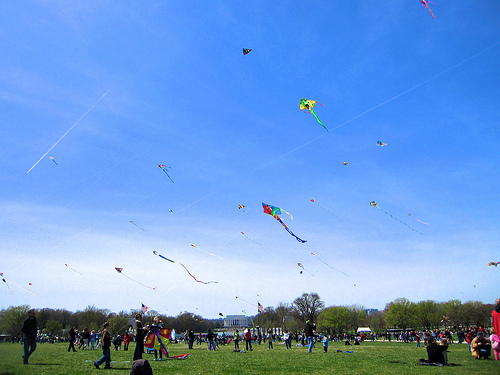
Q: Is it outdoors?
A: Yes, it is outdoors.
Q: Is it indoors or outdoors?
A: It is outdoors.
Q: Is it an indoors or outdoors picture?
A: It is outdoors.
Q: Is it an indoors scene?
A: No, it is outdoors.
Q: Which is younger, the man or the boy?
A: The boy is younger than the man.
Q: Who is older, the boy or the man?
A: The man is older than the boy.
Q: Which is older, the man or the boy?
A: The man is older than the boy.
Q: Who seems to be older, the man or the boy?
A: The man is older than the boy.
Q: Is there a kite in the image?
A: Yes, there is a kite.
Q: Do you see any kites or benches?
A: Yes, there is a kite.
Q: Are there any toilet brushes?
A: No, there are no toilet brushes.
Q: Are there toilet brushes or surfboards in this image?
A: No, there are no toilet brushes or surfboards.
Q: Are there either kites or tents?
A: Yes, there is a kite.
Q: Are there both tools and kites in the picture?
A: No, there is a kite but no tools.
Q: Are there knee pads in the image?
A: No, there are no knee pads.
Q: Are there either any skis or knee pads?
A: No, there are no knee pads or skis.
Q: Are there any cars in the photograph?
A: No, there are no cars.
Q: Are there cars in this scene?
A: No, there are no cars.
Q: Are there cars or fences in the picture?
A: No, there are no cars or fences.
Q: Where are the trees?
A: The trees are in the park.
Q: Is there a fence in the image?
A: No, there are no fences.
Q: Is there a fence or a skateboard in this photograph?
A: No, there are no fences or skateboards.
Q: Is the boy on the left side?
A: Yes, the boy is on the left of the image.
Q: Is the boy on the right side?
A: No, the boy is on the left of the image.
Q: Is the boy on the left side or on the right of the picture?
A: The boy is on the left of the image.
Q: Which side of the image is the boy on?
A: The boy is on the left of the image.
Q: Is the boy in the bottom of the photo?
A: Yes, the boy is in the bottom of the image.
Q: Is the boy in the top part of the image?
A: No, the boy is in the bottom of the image.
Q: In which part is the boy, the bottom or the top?
A: The boy is in the bottom of the image.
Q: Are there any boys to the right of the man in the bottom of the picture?
A: Yes, there is a boy to the right of the man.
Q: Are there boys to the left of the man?
A: No, the boy is to the right of the man.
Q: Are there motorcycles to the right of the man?
A: No, there is a boy to the right of the man.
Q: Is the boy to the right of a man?
A: Yes, the boy is to the right of a man.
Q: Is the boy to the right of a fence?
A: No, the boy is to the right of a man.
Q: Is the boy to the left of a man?
A: No, the boy is to the right of a man.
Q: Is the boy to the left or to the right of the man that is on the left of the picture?
A: The boy is to the right of the man.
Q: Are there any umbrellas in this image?
A: No, there are no umbrellas.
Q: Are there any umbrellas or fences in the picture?
A: No, there are no umbrellas or fences.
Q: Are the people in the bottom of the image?
A: Yes, the people are in the bottom of the image.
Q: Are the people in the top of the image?
A: No, the people are in the bottom of the image.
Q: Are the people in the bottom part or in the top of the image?
A: The people are in the bottom of the image.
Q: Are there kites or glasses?
A: Yes, there is a kite.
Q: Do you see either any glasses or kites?
A: Yes, there is a kite.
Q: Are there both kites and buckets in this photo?
A: No, there is a kite but no buckets.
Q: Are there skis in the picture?
A: No, there are no skis.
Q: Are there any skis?
A: No, there are no skis.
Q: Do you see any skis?
A: No, there are no skis.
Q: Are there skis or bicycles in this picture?
A: No, there are no skis or bicycles.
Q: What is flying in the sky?
A: The kite is flying in the sky.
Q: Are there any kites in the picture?
A: Yes, there is a kite.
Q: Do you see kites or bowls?
A: Yes, there is a kite.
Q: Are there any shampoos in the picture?
A: No, there are no shampoos.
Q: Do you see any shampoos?
A: No, there are no shampoos.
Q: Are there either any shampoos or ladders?
A: No, there are no shampoos or ladders.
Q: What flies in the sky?
A: The kite flies in the sky.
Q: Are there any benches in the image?
A: No, there are no benches.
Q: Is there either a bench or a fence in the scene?
A: No, there are no benches or fences.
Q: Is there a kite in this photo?
A: Yes, there is a kite.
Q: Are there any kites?
A: Yes, there is a kite.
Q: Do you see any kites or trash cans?
A: Yes, there is a kite.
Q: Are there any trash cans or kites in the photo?
A: Yes, there is a kite.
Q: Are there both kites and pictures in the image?
A: No, there is a kite but no pictures.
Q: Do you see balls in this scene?
A: No, there are no balls.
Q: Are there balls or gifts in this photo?
A: No, there are no balls or gifts.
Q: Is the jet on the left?
A: Yes, the jet is on the left of the image.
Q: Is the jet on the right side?
A: No, the jet is on the left of the image.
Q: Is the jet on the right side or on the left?
A: The jet is on the left of the image.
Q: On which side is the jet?
A: The jet is on the left of the image.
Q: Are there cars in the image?
A: No, there are no cars.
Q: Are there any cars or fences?
A: No, there are no cars or fences.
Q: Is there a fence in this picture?
A: No, there are no fences.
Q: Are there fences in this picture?
A: No, there are no fences.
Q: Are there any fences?
A: No, there are no fences.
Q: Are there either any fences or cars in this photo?
A: No, there are no fences or cars.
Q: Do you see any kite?
A: Yes, there is a kite.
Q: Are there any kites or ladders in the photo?
A: Yes, there is a kite.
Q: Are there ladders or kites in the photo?
A: Yes, there is a kite.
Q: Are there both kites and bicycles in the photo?
A: No, there is a kite but no bikes.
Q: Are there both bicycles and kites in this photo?
A: No, there is a kite but no bikes.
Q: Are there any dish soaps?
A: No, there are no dish soaps.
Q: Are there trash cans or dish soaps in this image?
A: No, there are no dish soaps or trash cans.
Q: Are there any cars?
A: No, there are no cars.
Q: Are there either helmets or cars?
A: No, there are no cars or helmets.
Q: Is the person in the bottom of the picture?
A: Yes, the person is in the bottom of the image.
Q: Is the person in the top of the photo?
A: No, the person is in the bottom of the image.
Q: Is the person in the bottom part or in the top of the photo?
A: The person is in the bottom of the image.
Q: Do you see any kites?
A: Yes, there is a kite.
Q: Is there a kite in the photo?
A: Yes, there is a kite.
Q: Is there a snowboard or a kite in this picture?
A: Yes, there is a kite.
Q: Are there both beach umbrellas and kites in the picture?
A: No, there is a kite but no beach umbrellas.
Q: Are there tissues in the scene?
A: No, there are no tissues.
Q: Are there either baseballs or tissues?
A: No, there are no tissues or baseballs.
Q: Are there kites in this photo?
A: Yes, there is a kite.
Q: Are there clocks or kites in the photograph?
A: Yes, there is a kite.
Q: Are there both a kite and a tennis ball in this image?
A: No, there is a kite but no tennis balls.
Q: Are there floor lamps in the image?
A: No, there are no floor lamps.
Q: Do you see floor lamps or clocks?
A: No, there are no floor lamps or clocks.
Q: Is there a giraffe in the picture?
A: No, there are no giraffes.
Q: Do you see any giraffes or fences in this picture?
A: No, there are no giraffes or fences.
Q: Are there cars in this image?
A: No, there are no cars.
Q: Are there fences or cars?
A: No, there are no cars or fences.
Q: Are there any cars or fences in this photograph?
A: No, there are no cars or fences.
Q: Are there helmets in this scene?
A: No, there are no helmets.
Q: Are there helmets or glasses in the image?
A: No, there are no helmets or glasses.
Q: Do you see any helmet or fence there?
A: No, there are no fences or helmets.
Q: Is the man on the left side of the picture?
A: Yes, the man is on the left of the image.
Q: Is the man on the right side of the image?
A: No, the man is on the left of the image.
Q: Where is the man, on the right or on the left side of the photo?
A: The man is on the left of the image.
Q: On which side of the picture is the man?
A: The man is on the left of the image.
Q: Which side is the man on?
A: The man is on the left of the image.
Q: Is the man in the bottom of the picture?
A: Yes, the man is in the bottom of the image.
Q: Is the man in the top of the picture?
A: No, the man is in the bottom of the image.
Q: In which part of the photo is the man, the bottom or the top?
A: The man is in the bottom of the image.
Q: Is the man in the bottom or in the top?
A: The man is in the bottom of the image.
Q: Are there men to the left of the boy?
A: Yes, there is a man to the left of the boy.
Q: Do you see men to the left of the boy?
A: Yes, there is a man to the left of the boy.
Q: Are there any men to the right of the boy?
A: No, the man is to the left of the boy.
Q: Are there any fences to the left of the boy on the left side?
A: No, there is a man to the left of the boy.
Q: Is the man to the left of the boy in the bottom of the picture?
A: Yes, the man is to the left of the boy.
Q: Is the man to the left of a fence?
A: No, the man is to the left of the boy.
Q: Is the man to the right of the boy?
A: No, the man is to the left of the boy.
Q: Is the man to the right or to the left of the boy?
A: The man is to the left of the boy.